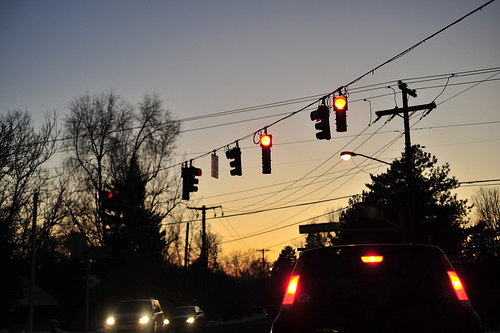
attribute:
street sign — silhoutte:
[296, 220, 366, 234]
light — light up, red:
[331, 93, 353, 138]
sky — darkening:
[9, 8, 492, 120]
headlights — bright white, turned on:
[100, 311, 198, 331]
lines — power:
[271, 112, 400, 218]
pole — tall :
[169, 176, 284, 273]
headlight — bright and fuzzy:
[136, 310, 150, 331]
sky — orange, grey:
[0, 0, 495, 275]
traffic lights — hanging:
[165, 86, 367, 211]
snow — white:
[194, 299, 267, 331]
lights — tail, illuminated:
[264, 247, 499, 329]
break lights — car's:
[276, 249, 471, 309]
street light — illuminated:
[337, 149, 394, 169]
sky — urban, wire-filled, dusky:
[137, 18, 329, 110]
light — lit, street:
[328, 140, 409, 186]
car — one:
[163, 303, 203, 331]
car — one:
[103, 297, 165, 332]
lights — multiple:
[98, 94, 351, 215]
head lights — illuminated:
[160, 314, 194, 331]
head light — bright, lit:
[136, 315, 151, 327]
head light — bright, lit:
[106, 315, 116, 330]